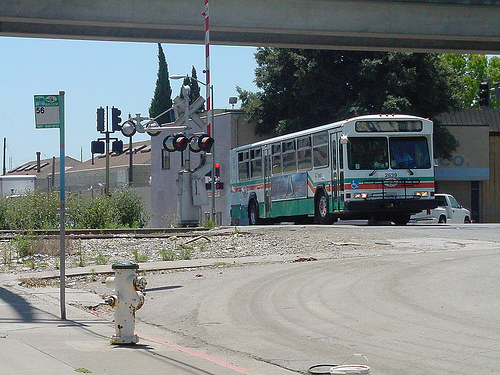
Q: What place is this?
A: It is a road.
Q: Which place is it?
A: It is a road.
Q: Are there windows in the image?
A: Yes, there is a window.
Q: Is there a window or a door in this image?
A: Yes, there is a window.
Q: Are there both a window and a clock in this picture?
A: No, there is a window but no clocks.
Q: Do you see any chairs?
A: No, there are no chairs.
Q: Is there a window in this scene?
A: Yes, there is a window.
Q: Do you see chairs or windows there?
A: Yes, there is a window.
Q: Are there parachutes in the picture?
A: No, there are no parachutes.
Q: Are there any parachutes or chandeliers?
A: No, there are no parachutes or chandeliers.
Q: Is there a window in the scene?
A: Yes, there is a window.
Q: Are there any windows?
A: Yes, there is a window.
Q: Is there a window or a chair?
A: Yes, there is a window.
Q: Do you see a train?
A: No, there are no trains.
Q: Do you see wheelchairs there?
A: No, there are no wheelchairs.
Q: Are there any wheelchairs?
A: No, there are no wheelchairs.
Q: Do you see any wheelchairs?
A: No, there are no wheelchairs.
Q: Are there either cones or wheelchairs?
A: No, there are no wheelchairs or cones.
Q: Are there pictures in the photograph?
A: No, there are no pictures.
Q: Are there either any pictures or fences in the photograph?
A: No, there are no pictures or fences.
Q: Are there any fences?
A: No, there are no fences.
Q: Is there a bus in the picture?
A: Yes, there is a bus.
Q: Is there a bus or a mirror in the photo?
A: Yes, there is a bus.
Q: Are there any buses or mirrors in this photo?
A: Yes, there is a bus.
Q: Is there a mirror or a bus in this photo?
A: Yes, there is a bus.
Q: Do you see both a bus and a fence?
A: No, there is a bus but no fences.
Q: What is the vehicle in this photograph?
A: The vehicle is a bus.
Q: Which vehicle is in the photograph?
A: The vehicle is a bus.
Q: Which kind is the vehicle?
A: The vehicle is a bus.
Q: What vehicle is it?
A: The vehicle is a bus.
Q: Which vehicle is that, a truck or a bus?
A: This is a bus.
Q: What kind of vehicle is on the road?
A: The vehicle is a bus.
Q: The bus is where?
A: The bus is on the road.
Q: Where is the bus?
A: The bus is on the road.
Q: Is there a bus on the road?
A: Yes, there is a bus on the road.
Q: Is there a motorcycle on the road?
A: No, there is a bus on the road.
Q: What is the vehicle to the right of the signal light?
A: The vehicle is a bus.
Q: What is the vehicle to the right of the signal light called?
A: The vehicle is a bus.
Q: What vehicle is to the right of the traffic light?
A: The vehicle is a bus.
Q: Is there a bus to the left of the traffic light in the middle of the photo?
A: No, the bus is to the right of the traffic light.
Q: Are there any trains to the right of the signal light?
A: No, there is a bus to the right of the signal light.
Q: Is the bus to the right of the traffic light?
A: Yes, the bus is to the right of the traffic light.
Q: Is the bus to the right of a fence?
A: No, the bus is to the right of the traffic light.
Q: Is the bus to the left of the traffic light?
A: No, the bus is to the right of the traffic light.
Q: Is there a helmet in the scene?
A: No, there are no helmets.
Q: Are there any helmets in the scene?
A: No, there are no helmets.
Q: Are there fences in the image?
A: No, there are no fences.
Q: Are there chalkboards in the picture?
A: No, there are no chalkboards.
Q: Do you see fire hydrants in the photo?
A: Yes, there is a fire hydrant.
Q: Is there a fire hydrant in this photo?
A: Yes, there is a fire hydrant.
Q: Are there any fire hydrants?
A: Yes, there is a fire hydrant.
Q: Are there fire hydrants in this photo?
A: Yes, there is a fire hydrant.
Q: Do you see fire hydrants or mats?
A: Yes, there is a fire hydrant.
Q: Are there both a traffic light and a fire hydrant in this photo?
A: Yes, there are both a fire hydrant and a traffic light.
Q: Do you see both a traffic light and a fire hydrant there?
A: Yes, there are both a fire hydrant and a traffic light.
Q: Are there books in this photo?
A: No, there are no books.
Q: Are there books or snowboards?
A: No, there are no books or snowboards.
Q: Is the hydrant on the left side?
A: Yes, the hydrant is on the left of the image.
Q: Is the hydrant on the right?
A: No, the hydrant is on the left of the image.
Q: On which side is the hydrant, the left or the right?
A: The hydrant is on the left of the image.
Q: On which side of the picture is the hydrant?
A: The hydrant is on the left of the image.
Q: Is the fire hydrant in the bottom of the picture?
A: Yes, the fire hydrant is in the bottom of the image.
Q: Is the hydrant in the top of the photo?
A: No, the hydrant is in the bottom of the image.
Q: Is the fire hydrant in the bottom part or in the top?
A: The fire hydrant is in the bottom of the image.